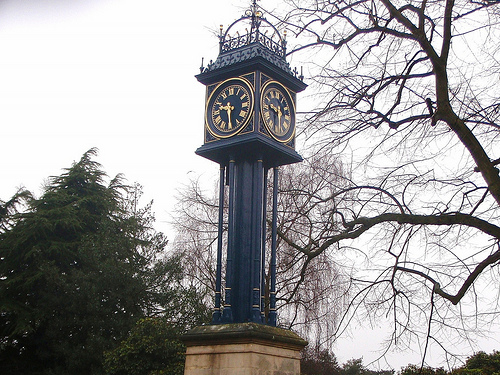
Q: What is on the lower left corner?
A: Evergreen tree.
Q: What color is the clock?
A: Blue and gold.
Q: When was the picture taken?
A: 9:30.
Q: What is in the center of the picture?
A: Clock.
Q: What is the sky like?
A: Overcast.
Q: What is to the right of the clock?
A: Leafless tree.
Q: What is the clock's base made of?
A: Concrete.